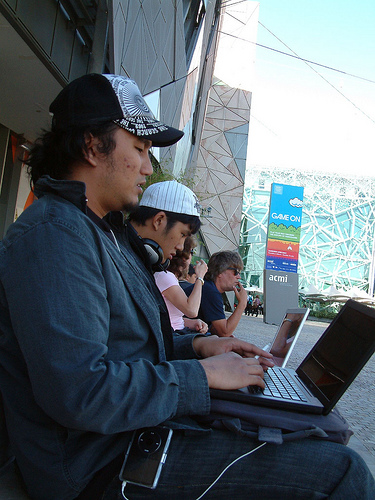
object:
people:
[179, 241, 253, 340]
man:
[125, 169, 225, 336]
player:
[152, 234, 219, 338]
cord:
[194, 440, 266, 500]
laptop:
[195, 289, 375, 421]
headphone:
[123, 214, 173, 270]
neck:
[75, 189, 132, 233]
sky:
[218, 0, 374, 185]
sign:
[262, 179, 305, 274]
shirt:
[153, 267, 190, 333]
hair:
[126, 202, 203, 237]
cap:
[48, 68, 185, 148]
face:
[156, 209, 187, 264]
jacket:
[183, 276, 227, 326]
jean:
[96, 422, 374, 499]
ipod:
[123, 415, 176, 466]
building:
[0, 1, 264, 303]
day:
[244, 0, 375, 177]